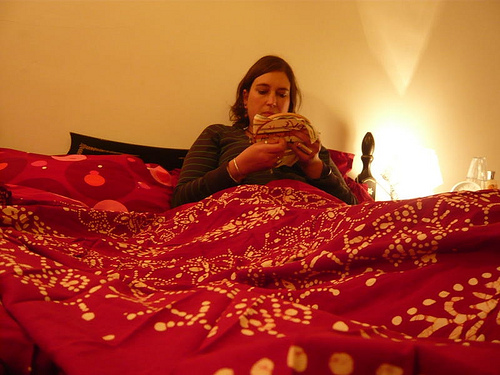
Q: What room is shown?
A: It is a bedroom.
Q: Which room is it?
A: It is a bedroom.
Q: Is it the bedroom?
A: Yes, it is the bedroom.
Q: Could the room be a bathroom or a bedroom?
A: It is a bedroom.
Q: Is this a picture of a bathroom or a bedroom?
A: It is showing a bedroom.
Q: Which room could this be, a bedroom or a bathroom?
A: It is a bedroom.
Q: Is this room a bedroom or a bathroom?
A: It is a bedroom.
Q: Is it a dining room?
A: No, it is a bedroom.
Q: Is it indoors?
A: Yes, it is indoors.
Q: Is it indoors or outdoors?
A: It is indoors.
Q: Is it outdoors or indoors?
A: It is indoors.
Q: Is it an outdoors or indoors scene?
A: It is indoors.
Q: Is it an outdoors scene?
A: No, it is indoors.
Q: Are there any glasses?
A: No, there are no glasses.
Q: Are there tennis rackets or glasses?
A: No, there are no glasses or tennis rackets.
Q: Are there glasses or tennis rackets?
A: No, there are no glasses or tennis rackets.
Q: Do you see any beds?
A: Yes, there is a bed.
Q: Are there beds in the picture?
A: Yes, there is a bed.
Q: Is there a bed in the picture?
A: Yes, there is a bed.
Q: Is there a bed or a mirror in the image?
A: Yes, there is a bed.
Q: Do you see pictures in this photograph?
A: No, there are no pictures.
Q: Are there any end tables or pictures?
A: No, there are no pictures or end tables.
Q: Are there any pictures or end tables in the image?
A: No, there are no pictures or end tables.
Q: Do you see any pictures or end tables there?
A: No, there are no pictures or end tables.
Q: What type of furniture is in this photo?
A: The furniture is a bed.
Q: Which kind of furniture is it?
A: The piece of furniture is a bed.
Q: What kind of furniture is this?
A: This is a bed.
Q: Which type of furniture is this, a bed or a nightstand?
A: This is a bed.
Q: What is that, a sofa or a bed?
A: That is a bed.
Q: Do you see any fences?
A: No, there are no fences.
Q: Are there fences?
A: No, there are no fences.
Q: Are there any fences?
A: No, there are no fences.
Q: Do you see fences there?
A: No, there are no fences.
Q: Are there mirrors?
A: No, there are no mirrors.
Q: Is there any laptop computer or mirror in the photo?
A: No, there are no mirrors or laptops.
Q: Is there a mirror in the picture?
A: No, there are no mirrors.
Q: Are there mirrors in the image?
A: No, there are no mirrors.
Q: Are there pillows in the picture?
A: Yes, there is a pillow.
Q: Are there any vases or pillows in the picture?
A: Yes, there is a pillow.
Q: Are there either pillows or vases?
A: Yes, there is a pillow.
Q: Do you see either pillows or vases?
A: Yes, there is a pillow.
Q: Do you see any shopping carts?
A: No, there are no shopping carts.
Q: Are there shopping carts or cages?
A: No, there are no shopping carts or cages.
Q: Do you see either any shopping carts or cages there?
A: No, there are no shopping carts or cages.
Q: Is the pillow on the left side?
A: Yes, the pillow is on the left of the image.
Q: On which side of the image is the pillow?
A: The pillow is on the left of the image.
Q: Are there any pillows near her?
A: Yes, there is a pillow near the lady.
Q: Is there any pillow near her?
A: Yes, there is a pillow near the lady.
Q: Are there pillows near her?
A: Yes, there is a pillow near the lady.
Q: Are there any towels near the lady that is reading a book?
A: No, there is a pillow near the lady.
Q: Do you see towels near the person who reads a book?
A: No, there is a pillow near the lady.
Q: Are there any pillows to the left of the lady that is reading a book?
A: Yes, there is a pillow to the left of the lady.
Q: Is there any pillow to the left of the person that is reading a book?
A: Yes, there is a pillow to the left of the lady.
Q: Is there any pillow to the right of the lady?
A: No, the pillow is to the left of the lady.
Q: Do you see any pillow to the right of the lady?
A: No, the pillow is to the left of the lady.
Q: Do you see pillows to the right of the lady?
A: No, the pillow is to the left of the lady.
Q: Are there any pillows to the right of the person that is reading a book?
A: No, the pillow is to the left of the lady.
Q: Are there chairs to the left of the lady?
A: No, there is a pillow to the left of the lady.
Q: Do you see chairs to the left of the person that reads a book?
A: No, there is a pillow to the left of the lady.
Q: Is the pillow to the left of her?
A: Yes, the pillow is to the left of the lady.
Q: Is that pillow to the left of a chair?
A: No, the pillow is to the left of the lady.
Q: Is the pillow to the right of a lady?
A: No, the pillow is to the left of a lady.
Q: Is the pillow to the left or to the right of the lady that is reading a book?
A: The pillow is to the left of the lady.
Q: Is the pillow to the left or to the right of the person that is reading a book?
A: The pillow is to the left of the lady.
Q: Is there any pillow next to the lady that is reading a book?
A: Yes, there is a pillow next to the lady.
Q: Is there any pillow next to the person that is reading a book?
A: Yes, there is a pillow next to the lady.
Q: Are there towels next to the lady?
A: No, there is a pillow next to the lady.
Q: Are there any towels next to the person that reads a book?
A: No, there is a pillow next to the lady.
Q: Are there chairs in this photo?
A: No, there are no chairs.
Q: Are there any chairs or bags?
A: No, there are no chairs or bags.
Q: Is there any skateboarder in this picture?
A: No, there are no skateboarders.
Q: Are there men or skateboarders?
A: No, there are no skateboarders or men.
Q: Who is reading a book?
A: The lady is reading a book.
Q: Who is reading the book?
A: The lady is reading a book.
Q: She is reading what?
A: The lady is reading a book.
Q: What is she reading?
A: The lady is reading a book.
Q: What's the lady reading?
A: The lady is reading a book.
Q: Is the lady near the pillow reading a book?
A: Yes, the lady is reading a book.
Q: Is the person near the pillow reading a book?
A: Yes, the lady is reading a book.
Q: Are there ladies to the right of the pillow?
A: Yes, there is a lady to the right of the pillow.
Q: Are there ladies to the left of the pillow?
A: No, the lady is to the right of the pillow.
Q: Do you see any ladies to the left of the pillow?
A: No, the lady is to the right of the pillow.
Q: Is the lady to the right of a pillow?
A: Yes, the lady is to the right of a pillow.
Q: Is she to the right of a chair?
A: No, the lady is to the right of a pillow.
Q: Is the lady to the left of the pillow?
A: No, the lady is to the right of the pillow.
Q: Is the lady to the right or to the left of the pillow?
A: The lady is to the right of the pillow.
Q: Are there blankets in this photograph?
A: Yes, there is a blanket.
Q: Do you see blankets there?
A: Yes, there is a blanket.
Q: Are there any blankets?
A: Yes, there is a blanket.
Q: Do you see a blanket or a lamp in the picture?
A: Yes, there is a blanket.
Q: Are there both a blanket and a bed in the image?
A: Yes, there are both a blanket and a bed.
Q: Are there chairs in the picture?
A: No, there are no chairs.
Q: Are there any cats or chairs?
A: No, there are no chairs or cats.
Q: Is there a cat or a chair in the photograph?
A: No, there are no chairs or cats.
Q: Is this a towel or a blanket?
A: This is a blanket.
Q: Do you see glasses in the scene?
A: No, there are no glasses.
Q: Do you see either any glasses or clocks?
A: No, there are no glasses or clocks.